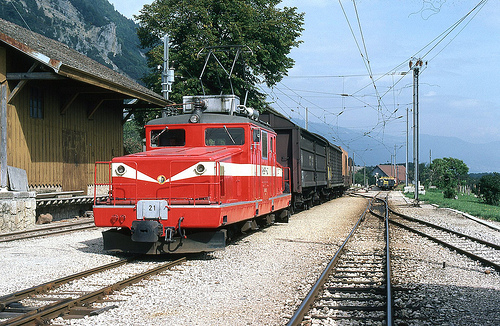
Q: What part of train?
A: Front.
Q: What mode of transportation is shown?
A: Train.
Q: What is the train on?
A: Tracks.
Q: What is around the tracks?
A: Gravel.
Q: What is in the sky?
A: Clouds.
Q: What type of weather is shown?
A: Cloudy.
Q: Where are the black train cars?
A: Behind the red train engine.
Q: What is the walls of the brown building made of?
A: Boards.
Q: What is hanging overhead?
A: Utility lines.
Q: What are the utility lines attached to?
A: Poles.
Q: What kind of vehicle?
A: Train.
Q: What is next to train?
A: Station.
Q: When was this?
A: Daytime.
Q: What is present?
A: A train.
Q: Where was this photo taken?
A: At a train station.